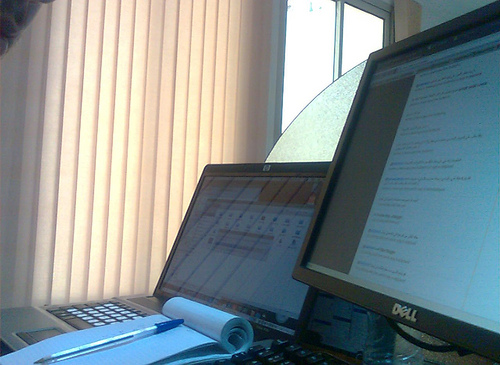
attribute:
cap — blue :
[153, 317, 173, 336]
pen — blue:
[86, 332, 138, 353]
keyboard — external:
[239, 335, 314, 359]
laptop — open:
[46, 131, 349, 357]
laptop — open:
[101, 140, 338, 360]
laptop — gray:
[11, 147, 300, 360]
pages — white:
[3, 295, 257, 363]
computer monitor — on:
[293, 17, 498, 326]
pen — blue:
[34, 304, 189, 364]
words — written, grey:
[388, 299, 420, 324]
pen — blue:
[35, 289, 200, 363]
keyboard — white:
[42, 302, 150, 327]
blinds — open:
[0, 1, 275, 308]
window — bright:
[279, 3, 390, 142]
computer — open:
[290, 1, 499, 344]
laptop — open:
[0, 161, 335, 363]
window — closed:
[281, 1, 393, 129]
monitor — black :
[312, 6, 499, 346]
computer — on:
[308, 74, 499, 181]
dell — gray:
[377, 301, 429, 330]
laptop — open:
[0, 160, 334, 344]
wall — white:
[1, 3, 281, 324]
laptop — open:
[5, 136, 332, 363]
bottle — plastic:
[327, 297, 437, 348]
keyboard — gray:
[38, 296, 164, 333]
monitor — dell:
[297, 10, 499, 357]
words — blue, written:
[220, 208, 299, 237]